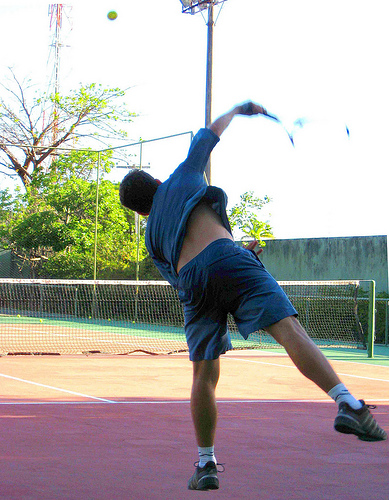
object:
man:
[119, 101, 386, 491]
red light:
[6, 258, 146, 362]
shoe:
[187, 461, 220, 491]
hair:
[119, 169, 159, 214]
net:
[1, 277, 367, 356]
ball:
[107, 10, 119, 21]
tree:
[0, 0, 141, 204]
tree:
[0, 148, 147, 277]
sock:
[327, 383, 361, 409]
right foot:
[334, 398, 389, 441]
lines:
[113, 395, 384, 407]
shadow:
[46, 396, 322, 496]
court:
[0, 238, 386, 493]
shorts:
[178, 238, 299, 361]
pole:
[367, 280, 375, 358]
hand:
[242, 100, 268, 115]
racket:
[242, 102, 349, 154]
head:
[119, 169, 158, 217]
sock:
[198, 446, 217, 468]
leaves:
[13, 151, 132, 250]